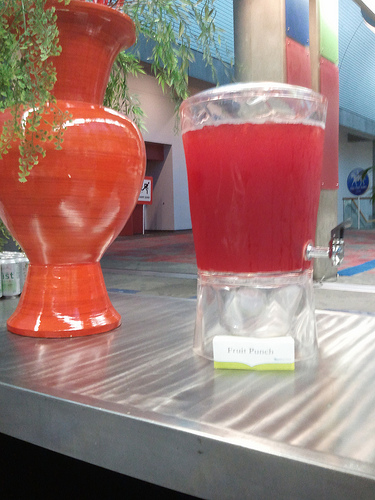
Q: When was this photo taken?
A: Outside, during the daytime.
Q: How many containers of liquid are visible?
A: One.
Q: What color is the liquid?
A: Red.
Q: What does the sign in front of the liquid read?
A: Fruit Punch.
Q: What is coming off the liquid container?
A: A drink spout.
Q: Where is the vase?
A: Next to the juice container.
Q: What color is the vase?
A: Orange.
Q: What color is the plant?
A: Green.